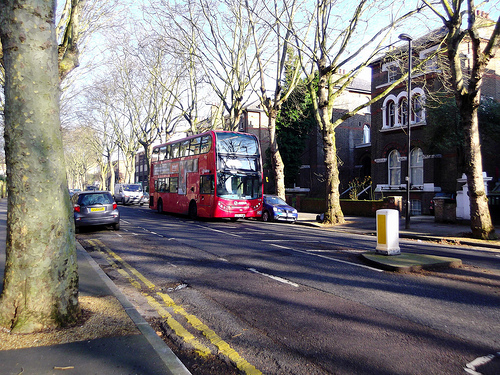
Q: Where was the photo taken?
A: It was taken at the street.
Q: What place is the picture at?
A: It is at the street.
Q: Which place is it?
A: It is a street.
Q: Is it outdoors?
A: Yes, it is outdoors.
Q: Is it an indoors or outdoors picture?
A: It is outdoors.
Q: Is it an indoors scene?
A: No, it is outdoors.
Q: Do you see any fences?
A: No, there are no fences.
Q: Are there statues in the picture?
A: No, there are no statues.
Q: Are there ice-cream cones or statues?
A: No, there are no statues or ice-cream cones.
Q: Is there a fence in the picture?
A: No, there are no fences.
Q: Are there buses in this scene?
A: Yes, there is a bus.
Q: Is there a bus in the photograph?
A: Yes, there is a bus.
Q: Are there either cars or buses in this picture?
A: Yes, there is a bus.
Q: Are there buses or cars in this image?
A: Yes, there is a bus.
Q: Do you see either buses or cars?
A: Yes, there is a bus.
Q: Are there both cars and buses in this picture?
A: Yes, there are both a bus and a car.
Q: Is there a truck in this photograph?
A: No, there are no trucks.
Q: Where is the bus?
A: The bus is on the street.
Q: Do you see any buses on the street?
A: Yes, there is a bus on the street.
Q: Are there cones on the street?
A: No, there is a bus on the street.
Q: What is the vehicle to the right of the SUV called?
A: The vehicle is a bus.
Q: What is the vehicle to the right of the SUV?
A: The vehicle is a bus.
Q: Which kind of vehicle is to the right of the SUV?
A: The vehicle is a bus.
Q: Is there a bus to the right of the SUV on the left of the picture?
A: Yes, there is a bus to the right of the SUV.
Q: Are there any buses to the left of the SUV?
A: No, the bus is to the right of the SUV.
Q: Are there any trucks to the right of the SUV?
A: No, there is a bus to the right of the SUV.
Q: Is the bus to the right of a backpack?
A: No, the bus is to the right of the SUV.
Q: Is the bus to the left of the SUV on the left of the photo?
A: No, the bus is to the right of the SUV.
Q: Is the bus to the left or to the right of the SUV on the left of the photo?
A: The bus is to the right of the SUV.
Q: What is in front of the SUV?
A: The bus is in front of the SUV.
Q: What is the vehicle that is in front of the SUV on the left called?
A: The vehicle is a bus.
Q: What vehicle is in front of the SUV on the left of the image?
A: The vehicle is a bus.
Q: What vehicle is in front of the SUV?
A: The vehicle is a bus.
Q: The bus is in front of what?
A: The bus is in front of the SUV.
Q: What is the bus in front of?
A: The bus is in front of the SUV.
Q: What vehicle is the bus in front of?
A: The bus is in front of the SUV.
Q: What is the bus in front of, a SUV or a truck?
A: The bus is in front of a SUV.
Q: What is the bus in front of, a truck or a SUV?
A: The bus is in front of a SUV.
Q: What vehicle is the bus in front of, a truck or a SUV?
A: The bus is in front of a SUV.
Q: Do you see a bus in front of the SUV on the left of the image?
A: Yes, there is a bus in front of the SUV.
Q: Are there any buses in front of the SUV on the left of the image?
A: Yes, there is a bus in front of the SUV.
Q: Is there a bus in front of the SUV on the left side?
A: Yes, there is a bus in front of the SUV.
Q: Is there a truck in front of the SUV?
A: No, there is a bus in front of the SUV.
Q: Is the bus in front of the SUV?
A: Yes, the bus is in front of the SUV.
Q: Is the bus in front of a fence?
A: No, the bus is in front of the SUV.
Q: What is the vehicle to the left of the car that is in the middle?
A: The vehicle is a bus.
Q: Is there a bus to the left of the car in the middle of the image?
A: Yes, there is a bus to the left of the car.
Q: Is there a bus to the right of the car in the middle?
A: No, the bus is to the left of the car.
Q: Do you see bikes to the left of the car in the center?
A: No, there is a bus to the left of the car.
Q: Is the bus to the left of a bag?
A: No, the bus is to the left of the car.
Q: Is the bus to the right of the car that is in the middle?
A: No, the bus is to the left of the car.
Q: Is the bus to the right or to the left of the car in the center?
A: The bus is to the left of the car.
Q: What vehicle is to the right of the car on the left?
A: The vehicle is a bus.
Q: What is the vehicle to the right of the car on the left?
A: The vehicle is a bus.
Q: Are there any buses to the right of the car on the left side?
A: Yes, there is a bus to the right of the car.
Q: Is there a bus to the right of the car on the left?
A: Yes, there is a bus to the right of the car.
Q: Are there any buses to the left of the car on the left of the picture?
A: No, the bus is to the right of the car.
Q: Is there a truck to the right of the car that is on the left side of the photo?
A: No, there is a bus to the right of the car.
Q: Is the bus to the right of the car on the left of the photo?
A: Yes, the bus is to the right of the car.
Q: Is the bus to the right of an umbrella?
A: No, the bus is to the right of the car.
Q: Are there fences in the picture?
A: No, there are no fences.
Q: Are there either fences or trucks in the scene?
A: No, there are no fences or trucks.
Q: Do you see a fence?
A: No, there are no fences.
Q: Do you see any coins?
A: No, there are no coins.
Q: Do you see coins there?
A: No, there are no coins.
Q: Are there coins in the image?
A: No, there are no coins.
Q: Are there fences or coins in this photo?
A: No, there are no coins or fences.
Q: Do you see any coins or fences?
A: No, there are no coins or fences.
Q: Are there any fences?
A: No, there are no fences.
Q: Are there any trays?
A: No, there are no trays.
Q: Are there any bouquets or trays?
A: No, there are no trays or bouquets.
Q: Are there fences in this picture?
A: No, there are no fences.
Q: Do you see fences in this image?
A: No, there are no fences.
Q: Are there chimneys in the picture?
A: No, there are no chimneys.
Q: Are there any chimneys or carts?
A: No, there are no chimneys or carts.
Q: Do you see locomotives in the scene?
A: No, there are no locomotives.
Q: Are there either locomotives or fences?
A: No, there are no locomotives or fences.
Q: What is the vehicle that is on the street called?
A: The vehicle is a car.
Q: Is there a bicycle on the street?
A: No, there is a car on the street.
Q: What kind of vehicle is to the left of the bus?
A: The vehicle is a car.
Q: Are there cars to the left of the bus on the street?
A: Yes, there is a car to the left of the bus.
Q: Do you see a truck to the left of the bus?
A: No, there is a car to the left of the bus.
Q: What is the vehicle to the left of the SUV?
A: The vehicle is a car.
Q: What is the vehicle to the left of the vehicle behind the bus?
A: The vehicle is a car.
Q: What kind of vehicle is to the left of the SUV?
A: The vehicle is a car.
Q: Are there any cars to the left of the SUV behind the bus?
A: Yes, there is a car to the left of the SUV.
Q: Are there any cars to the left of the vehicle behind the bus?
A: Yes, there is a car to the left of the SUV.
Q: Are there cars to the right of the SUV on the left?
A: No, the car is to the left of the SUV.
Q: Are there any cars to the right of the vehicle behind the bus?
A: No, the car is to the left of the SUV.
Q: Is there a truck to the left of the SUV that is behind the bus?
A: No, there is a car to the left of the SUV.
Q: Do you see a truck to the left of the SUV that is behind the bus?
A: No, there is a car to the left of the SUV.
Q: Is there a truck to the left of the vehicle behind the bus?
A: No, there is a car to the left of the SUV.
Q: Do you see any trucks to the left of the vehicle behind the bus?
A: No, there is a car to the left of the SUV.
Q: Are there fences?
A: No, there are no fences.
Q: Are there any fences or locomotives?
A: No, there are no fences or locomotives.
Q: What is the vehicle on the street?
A: The vehicle is a car.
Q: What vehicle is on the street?
A: The vehicle is a car.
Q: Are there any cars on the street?
A: Yes, there is a car on the street.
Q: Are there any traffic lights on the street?
A: No, there is a car on the street.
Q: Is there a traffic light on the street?
A: No, there is a car on the street.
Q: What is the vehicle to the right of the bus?
A: The vehicle is a car.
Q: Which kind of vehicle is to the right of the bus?
A: The vehicle is a car.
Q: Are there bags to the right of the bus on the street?
A: No, there is a car to the right of the bus.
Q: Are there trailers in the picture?
A: No, there are no trailers.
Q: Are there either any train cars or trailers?
A: No, there are no trailers or train cars.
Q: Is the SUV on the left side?
A: Yes, the SUV is on the left of the image.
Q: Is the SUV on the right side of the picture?
A: No, the SUV is on the left of the image.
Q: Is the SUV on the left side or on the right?
A: The SUV is on the left of the image.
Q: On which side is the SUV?
A: The SUV is on the left of the image.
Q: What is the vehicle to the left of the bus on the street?
A: The vehicle is a SUV.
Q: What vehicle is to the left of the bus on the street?
A: The vehicle is a SUV.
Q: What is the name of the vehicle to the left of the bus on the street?
A: The vehicle is a SUV.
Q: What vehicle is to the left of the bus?
A: The vehicle is a SUV.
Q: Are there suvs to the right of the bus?
A: No, the SUV is to the left of the bus.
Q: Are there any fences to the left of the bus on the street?
A: No, there is a SUV to the left of the bus.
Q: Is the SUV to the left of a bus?
A: Yes, the SUV is to the left of a bus.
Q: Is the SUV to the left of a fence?
A: No, the SUV is to the left of a bus.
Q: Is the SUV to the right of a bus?
A: No, the SUV is to the left of a bus.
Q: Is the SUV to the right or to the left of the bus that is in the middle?
A: The SUV is to the left of the bus.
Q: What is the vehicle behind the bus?
A: The vehicle is a SUV.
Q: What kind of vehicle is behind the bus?
A: The vehicle is a SUV.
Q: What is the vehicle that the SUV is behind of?
A: The vehicle is a bus.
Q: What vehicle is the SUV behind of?
A: The SUV is behind the bus.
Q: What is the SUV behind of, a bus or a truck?
A: The SUV is behind a bus.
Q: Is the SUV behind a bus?
A: Yes, the SUV is behind a bus.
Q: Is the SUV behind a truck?
A: No, the SUV is behind a bus.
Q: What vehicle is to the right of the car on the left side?
A: The vehicle is a SUV.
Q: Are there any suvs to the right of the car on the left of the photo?
A: Yes, there is a SUV to the right of the car.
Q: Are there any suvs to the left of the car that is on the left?
A: No, the SUV is to the right of the car.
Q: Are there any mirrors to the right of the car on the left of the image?
A: No, there is a SUV to the right of the car.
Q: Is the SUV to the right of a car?
A: Yes, the SUV is to the right of a car.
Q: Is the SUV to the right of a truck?
A: No, the SUV is to the right of a car.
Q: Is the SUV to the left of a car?
A: No, the SUV is to the right of a car.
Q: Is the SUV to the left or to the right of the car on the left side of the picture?
A: The SUV is to the right of the car.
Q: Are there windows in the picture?
A: Yes, there is a window.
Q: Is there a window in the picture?
A: Yes, there is a window.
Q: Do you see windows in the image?
A: Yes, there is a window.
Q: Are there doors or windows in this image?
A: Yes, there is a window.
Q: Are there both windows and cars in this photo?
A: Yes, there are both a window and a car.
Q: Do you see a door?
A: No, there are no doors.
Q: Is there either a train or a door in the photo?
A: No, there are no doors or trains.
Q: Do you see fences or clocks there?
A: No, there are no fences or clocks.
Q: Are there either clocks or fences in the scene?
A: No, there are no fences or clocks.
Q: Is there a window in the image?
A: Yes, there is a window.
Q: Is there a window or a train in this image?
A: Yes, there is a window.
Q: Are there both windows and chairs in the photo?
A: No, there is a window but no chairs.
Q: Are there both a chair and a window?
A: No, there is a window but no chairs.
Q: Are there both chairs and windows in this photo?
A: No, there is a window but no chairs.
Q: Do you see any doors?
A: No, there are no doors.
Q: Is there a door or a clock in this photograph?
A: No, there are no doors or clocks.